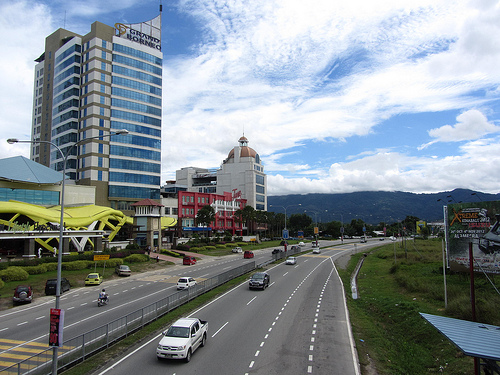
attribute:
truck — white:
[152, 317, 208, 363]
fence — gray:
[121, 299, 171, 328]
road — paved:
[128, 264, 375, 374]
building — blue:
[47, 32, 173, 190]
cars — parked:
[8, 254, 146, 292]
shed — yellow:
[9, 200, 128, 234]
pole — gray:
[47, 168, 68, 313]